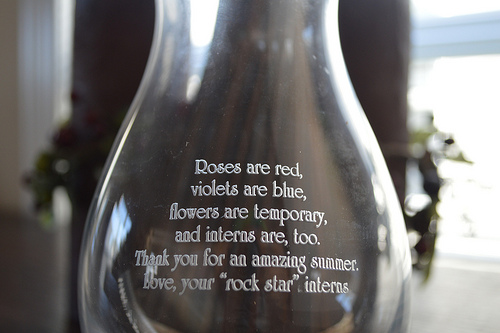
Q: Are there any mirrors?
A: No, there are no mirrors.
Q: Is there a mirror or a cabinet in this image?
A: No, there are no mirrors or cabinets.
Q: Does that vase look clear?
A: Yes, the vase is clear.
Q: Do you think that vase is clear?
A: Yes, the vase is clear.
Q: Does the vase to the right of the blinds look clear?
A: Yes, the vase is clear.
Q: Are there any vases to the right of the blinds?
A: Yes, there is a vase to the right of the blinds.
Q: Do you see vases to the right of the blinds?
A: Yes, there is a vase to the right of the blinds.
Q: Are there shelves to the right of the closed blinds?
A: No, there is a vase to the right of the blinds.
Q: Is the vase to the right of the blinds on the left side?
A: Yes, the vase is to the right of the blinds.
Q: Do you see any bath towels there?
A: No, there are no bath towels.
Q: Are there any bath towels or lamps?
A: No, there are no bath towels or lamps.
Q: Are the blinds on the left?
A: Yes, the blinds are on the left of the image.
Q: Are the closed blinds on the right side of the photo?
A: No, the blinds are on the left of the image.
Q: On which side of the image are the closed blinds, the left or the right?
A: The blinds are on the left of the image.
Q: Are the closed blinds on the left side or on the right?
A: The blinds are on the left of the image.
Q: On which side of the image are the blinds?
A: The blinds are on the left of the image.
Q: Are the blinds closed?
A: Yes, the blinds are closed.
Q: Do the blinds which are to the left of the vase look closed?
A: Yes, the blinds are closed.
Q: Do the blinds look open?
A: No, the blinds are closed.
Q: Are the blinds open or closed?
A: The blinds are closed.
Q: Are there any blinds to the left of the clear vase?
A: Yes, there are blinds to the left of the vase.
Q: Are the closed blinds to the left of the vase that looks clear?
A: Yes, the blinds are to the left of the vase.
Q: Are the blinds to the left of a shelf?
A: No, the blinds are to the left of the vase.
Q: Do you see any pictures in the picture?
A: No, there are no pictures.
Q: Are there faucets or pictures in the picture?
A: No, there are no pictures or faucets.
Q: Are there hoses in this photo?
A: No, there are no hoses.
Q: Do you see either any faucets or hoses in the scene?
A: No, there are no hoses or faucets.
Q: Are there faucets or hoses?
A: No, there are no hoses or faucets.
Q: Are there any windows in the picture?
A: Yes, there is a window.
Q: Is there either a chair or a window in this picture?
A: Yes, there is a window.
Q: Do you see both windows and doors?
A: No, there is a window but no doors.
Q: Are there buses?
A: No, there are no buses.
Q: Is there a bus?
A: No, there are no buses.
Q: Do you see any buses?
A: No, there are no buses.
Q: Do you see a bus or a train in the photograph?
A: No, there are no buses or trains.